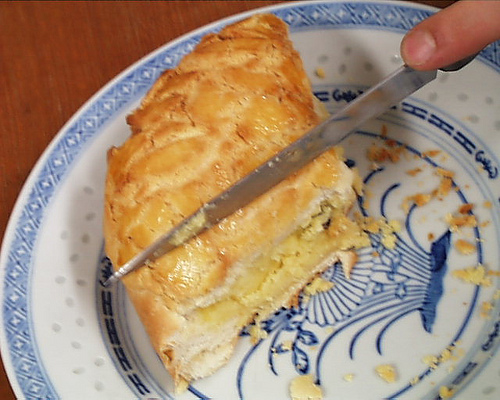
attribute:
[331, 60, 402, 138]
knife — cutting, metal, white, silver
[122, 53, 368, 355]
pie — brown, yellow, close, cutting, round, ready, done, moist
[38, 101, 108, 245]
plate — white, blue, round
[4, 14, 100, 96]
table — brown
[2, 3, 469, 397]
table — wooden